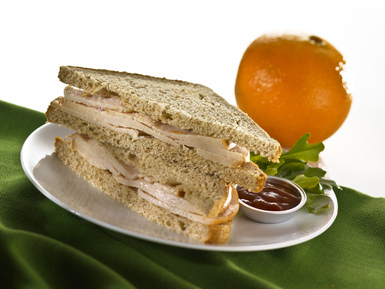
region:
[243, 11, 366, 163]
orange next to plate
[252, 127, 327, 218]
green vegetable on plate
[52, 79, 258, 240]
sandwich sliced in half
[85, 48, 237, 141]
light brown wheat bread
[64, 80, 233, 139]
pink meat in sandwich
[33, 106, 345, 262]
white and round plate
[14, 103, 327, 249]
plate on green cover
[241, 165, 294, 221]
small white souffle cup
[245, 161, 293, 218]
cup contains brown sauce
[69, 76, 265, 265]
diagonally sliced turkey sandwich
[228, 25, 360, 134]
orange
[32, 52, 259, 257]
two halves of a turkey sandwich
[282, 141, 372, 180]
green garnish on plate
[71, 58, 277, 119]
triangular slice of bread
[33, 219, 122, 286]
green table cloth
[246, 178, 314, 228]
little dish of sauce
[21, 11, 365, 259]
sandwich and orange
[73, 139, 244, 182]
turkey slices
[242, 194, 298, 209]
dark red sauce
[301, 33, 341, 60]
navel of orange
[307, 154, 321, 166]
lettuce on the plate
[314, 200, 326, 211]
lettuce on the plate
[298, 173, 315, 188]
lettuce on the plate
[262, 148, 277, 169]
edge of the bread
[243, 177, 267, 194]
edge of the bread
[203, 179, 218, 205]
edge of the bread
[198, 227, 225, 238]
edge of the bread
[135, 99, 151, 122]
edge of the bread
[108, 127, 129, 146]
edge of the bread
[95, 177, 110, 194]
edge of the bread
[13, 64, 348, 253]
Plate of sandwich on a table.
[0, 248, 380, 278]
Table covered with green tablecloth.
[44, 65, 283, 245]
Bread cut in triangle shape.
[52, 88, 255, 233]
Bread stuffed with sliced turkey.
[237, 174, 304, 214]
Sauce in a small container.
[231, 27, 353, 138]
An orange next to the plate.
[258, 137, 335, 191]
Few green leaves to decorate the plate.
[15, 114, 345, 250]
Plate is round shaped.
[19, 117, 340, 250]
Sandwich plate is white.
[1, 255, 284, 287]
The green tablecloth is wrinkled.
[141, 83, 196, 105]
Part of whole wheat bread slice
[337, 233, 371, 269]
Part of green table cover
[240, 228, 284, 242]
Part of white serving plate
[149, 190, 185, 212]
Part of meat deli slice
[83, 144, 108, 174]
Part of meat deli slice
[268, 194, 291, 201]
Part of deli sauce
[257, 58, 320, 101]
Ripe Florida orange fruit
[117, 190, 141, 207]
Part of whole wheat bread slice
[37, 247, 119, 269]
Part of green table cloth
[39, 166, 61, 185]
Part of white serving plate